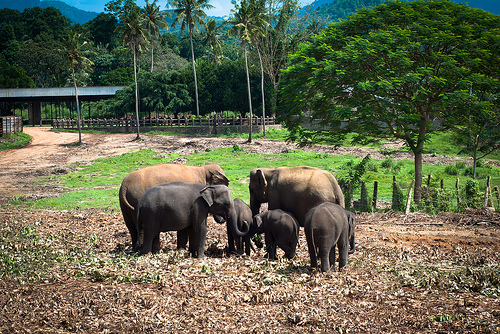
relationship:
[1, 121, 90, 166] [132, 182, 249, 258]
road for elephant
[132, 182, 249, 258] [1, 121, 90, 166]
elephant walk on road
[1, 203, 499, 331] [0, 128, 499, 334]
foliage on enclosure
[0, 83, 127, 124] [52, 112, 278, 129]
enclosure behind fence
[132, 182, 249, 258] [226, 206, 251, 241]
elephant has trunk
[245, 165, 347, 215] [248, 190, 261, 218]
elephant has trunk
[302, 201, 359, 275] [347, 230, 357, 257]
elephant has trunk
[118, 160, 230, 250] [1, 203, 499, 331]
elephant on foliage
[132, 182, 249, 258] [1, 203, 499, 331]
elephant on foliage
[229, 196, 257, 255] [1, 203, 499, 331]
elephant on foliage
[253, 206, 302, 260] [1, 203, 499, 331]
elephant on foliage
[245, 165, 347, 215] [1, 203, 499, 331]
elephant on foliage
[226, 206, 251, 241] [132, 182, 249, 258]
trunk of elephant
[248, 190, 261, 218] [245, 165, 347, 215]
trunk of elephant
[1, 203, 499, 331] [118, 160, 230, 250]
foliage around elephant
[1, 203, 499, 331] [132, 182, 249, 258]
foliage around elephant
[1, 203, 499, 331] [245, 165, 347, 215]
foliage around elephant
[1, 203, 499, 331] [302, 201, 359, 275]
foliage around elephant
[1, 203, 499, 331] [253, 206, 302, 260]
foliage around elephant